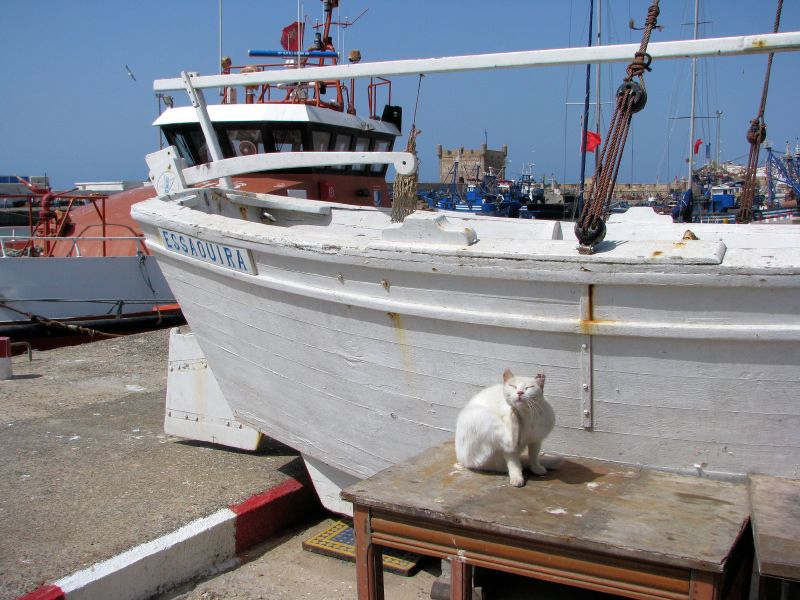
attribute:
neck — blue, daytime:
[498, 370, 551, 406]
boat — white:
[132, 20, 797, 577]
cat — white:
[452, 346, 589, 496]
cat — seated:
[451, 367, 555, 477]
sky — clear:
[9, 4, 164, 191]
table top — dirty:
[342, 432, 756, 568]